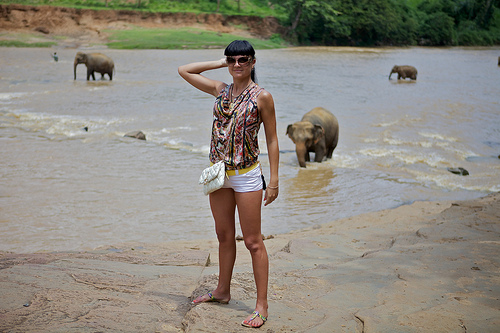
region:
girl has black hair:
[207, 14, 261, 65]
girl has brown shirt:
[220, 68, 258, 163]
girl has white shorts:
[205, 158, 286, 202]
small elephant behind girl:
[277, 98, 331, 160]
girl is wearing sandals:
[197, 279, 264, 327]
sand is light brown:
[314, 208, 496, 318]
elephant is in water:
[275, 84, 359, 176]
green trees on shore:
[291, 2, 493, 49]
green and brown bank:
[51, 12, 208, 33]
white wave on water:
[25, 89, 185, 157]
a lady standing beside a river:
[191, 12, 323, 327]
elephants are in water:
[295, 57, 482, 180]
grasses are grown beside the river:
[110, 16, 278, 45]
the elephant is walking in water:
[292, 84, 365, 190]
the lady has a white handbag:
[162, 80, 259, 326]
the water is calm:
[370, 98, 497, 160]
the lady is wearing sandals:
[182, 257, 269, 332]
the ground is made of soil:
[283, 192, 463, 332]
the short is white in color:
[217, 163, 272, 204]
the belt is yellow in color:
[225, 152, 270, 194]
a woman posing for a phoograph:
[193, 38, 283, 325]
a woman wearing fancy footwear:
[187, 282, 270, 331]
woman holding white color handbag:
[195, 160, 229, 190]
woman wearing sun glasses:
[226, 53, 252, 67]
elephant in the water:
[291, 100, 344, 173]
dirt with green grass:
[93, 10, 218, 47]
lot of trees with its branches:
[303, 13, 485, 40]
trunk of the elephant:
[291, 146, 308, 167]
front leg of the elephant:
[313, 152, 328, 167]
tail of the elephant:
[111, 65, 120, 77]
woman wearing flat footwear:
[242, 310, 263, 328]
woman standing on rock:
[190, 303, 227, 319]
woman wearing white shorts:
[227, 165, 258, 190]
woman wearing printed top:
[210, 93, 255, 151]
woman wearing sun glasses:
[225, 55, 248, 63]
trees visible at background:
[295, 1, 466, 42]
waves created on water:
[370, 131, 435, 186]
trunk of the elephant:
[295, 147, 305, 168]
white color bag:
[196, 161, 226, 193]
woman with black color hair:
[223, 40, 254, 55]